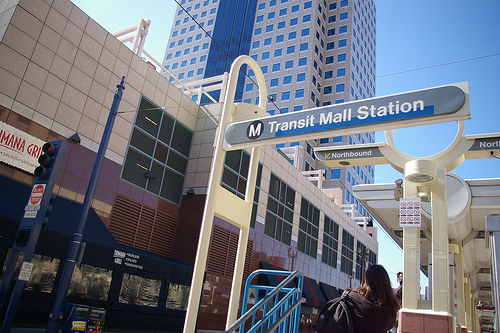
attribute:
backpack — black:
[314, 288, 355, 332]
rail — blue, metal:
[221, 267, 303, 331]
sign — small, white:
[23, 184, 48, 220]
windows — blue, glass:
[168, 3, 396, 218]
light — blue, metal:
[0, 140, 68, 331]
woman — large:
[322, 263, 403, 332]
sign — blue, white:
[223, 79, 474, 150]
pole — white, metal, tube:
[179, 53, 269, 331]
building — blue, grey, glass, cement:
[159, 0, 378, 177]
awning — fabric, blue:
[3, 174, 208, 290]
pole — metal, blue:
[49, 75, 136, 332]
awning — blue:
[262, 260, 362, 316]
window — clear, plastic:
[116, 271, 166, 312]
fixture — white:
[403, 158, 439, 186]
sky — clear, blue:
[85, 1, 499, 183]